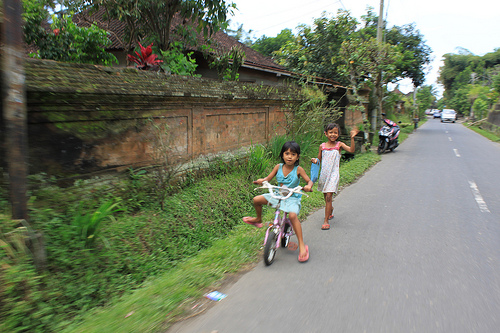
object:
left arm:
[341, 137, 355, 152]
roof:
[24, 58, 308, 102]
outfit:
[262, 162, 303, 215]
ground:
[0, 115, 500, 333]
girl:
[311, 123, 360, 230]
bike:
[252, 181, 313, 266]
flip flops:
[242, 216, 262, 228]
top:
[274, 163, 302, 199]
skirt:
[262, 192, 301, 216]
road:
[167, 118, 499, 333]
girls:
[242, 141, 313, 262]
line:
[468, 180, 490, 213]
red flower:
[127, 40, 163, 71]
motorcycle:
[378, 113, 402, 155]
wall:
[0, 107, 295, 229]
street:
[159, 87, 499, 332]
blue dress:
[262, 163, 303, 216]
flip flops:
[298, 244, 309, 262]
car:
[439, 107, 457, 123]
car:
[433, 109, 442, 118]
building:
[0, 0, 371, 224]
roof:
[23, 0, 341, 87]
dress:
[317, 141, 342, 194]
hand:
[350, 127, 361, 138]